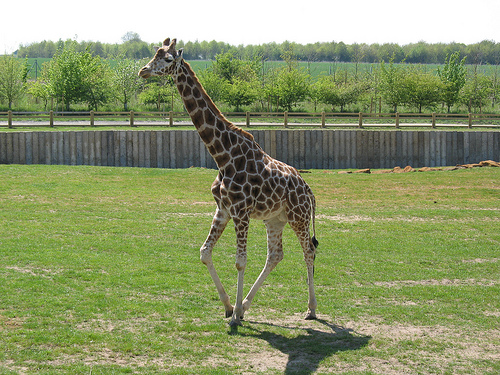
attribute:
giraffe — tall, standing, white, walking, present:
[135, 36, 320, 328]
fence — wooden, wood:
[0, 109, 499, 129]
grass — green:
[0, 161, 499, 374]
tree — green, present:
[38, 44, 101, 114]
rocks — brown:
[459, 158, 497, 171]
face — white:
[137, 55, 174, 80]